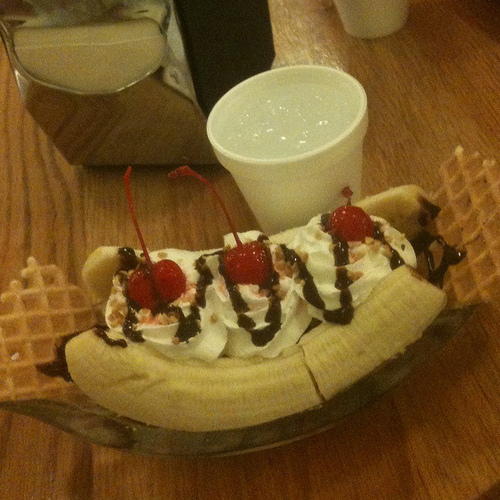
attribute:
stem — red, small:
[120, 164, 158, 272]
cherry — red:
[123, 163, 189, 305]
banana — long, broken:
[64, 262, 446, 435]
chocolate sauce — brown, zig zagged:
[37, 196, 466, 382]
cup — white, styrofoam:
[205, 62, 369, 234]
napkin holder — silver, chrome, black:
[0, 0, 275, 172]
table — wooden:
[0, 0, 499, 499]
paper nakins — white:
[4, 19, 164, 94]